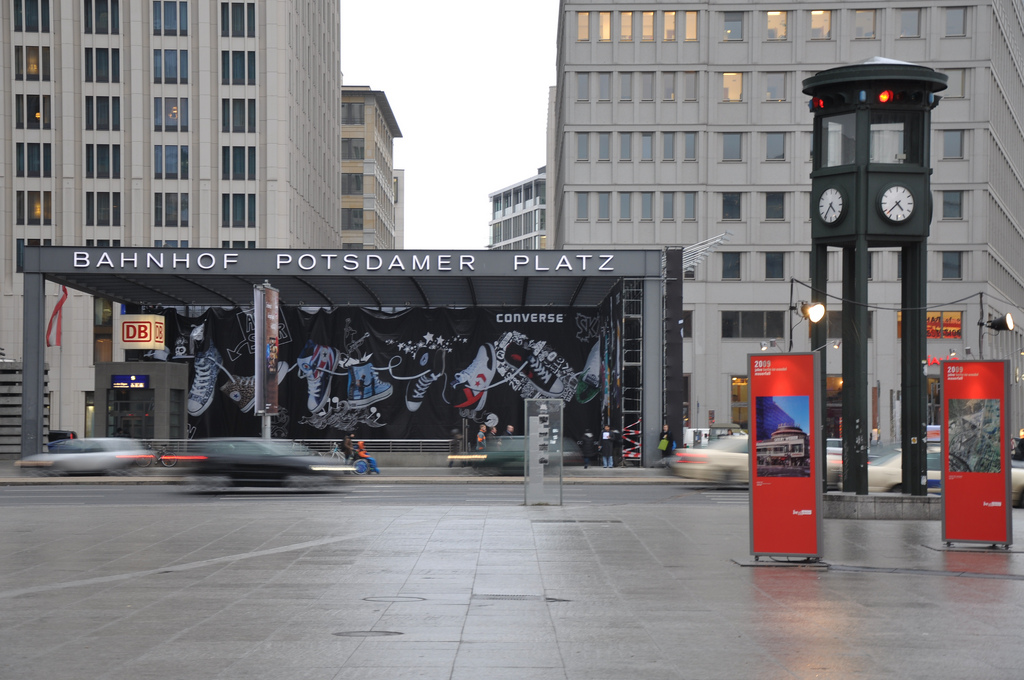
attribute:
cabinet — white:
[215, 40, 251, 85]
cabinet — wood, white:
[725, 312, 792, 336]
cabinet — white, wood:
[719, 250, 740, 280]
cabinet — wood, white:
[766, 239, 789, 279]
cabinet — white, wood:
[945, 247, 961, 280]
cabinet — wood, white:
[943, 191, 964, 224]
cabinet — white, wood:
[940, 128, 966, 167]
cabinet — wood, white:
[939, 68, 962, 101]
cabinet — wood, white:
[937, 4, 966, 36]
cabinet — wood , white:
[889, 2, 921, 37]